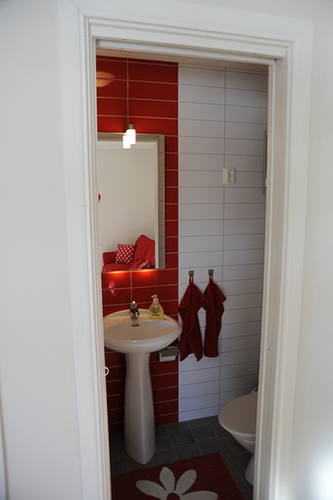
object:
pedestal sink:
[103, 305, 183, 465]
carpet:
[111, 448, 249, 500]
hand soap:
[148, 295, 164, 322]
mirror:
[96, 128, 164, 271]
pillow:
[114, 243, 136, 264]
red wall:
[95, 56, 178, 435]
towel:
[178, 271, 209, 361]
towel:
[203, 268, 227, 358]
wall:
[98, 56, 269, 435]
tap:
[129, 299, 139, 319]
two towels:
[178, 276, 229, 363]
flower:
[135, 465, 218, 500]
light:
[121, 123, 137, 150]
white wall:
[178, 63, 268, 425]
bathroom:
[0, 0, 333, 499]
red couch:
[103, 234, 156, 271]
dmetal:
[129, 299, 140, 322]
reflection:
[102, 233, 155, 270]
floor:
[109, 412, 253, 500]